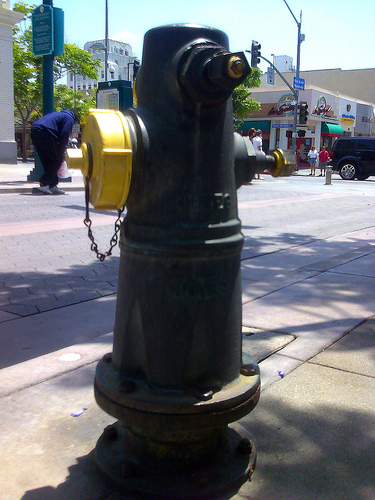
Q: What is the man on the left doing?
A: Bending Over.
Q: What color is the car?
A: Black.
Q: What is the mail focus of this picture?
A: A hydrant.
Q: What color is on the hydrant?
A: Yellow.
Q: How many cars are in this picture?
A: One.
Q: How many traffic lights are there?
A: One.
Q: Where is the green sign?
A: On the left hand pole.